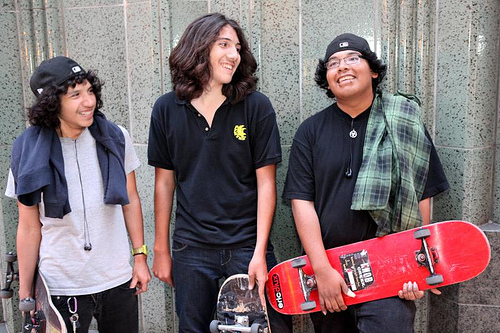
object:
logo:
[233, 122, 248, 142]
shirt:
[147, 86, 282, 250]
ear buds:
[73, 142, 94, 252]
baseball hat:
[30, 55, 87, 99]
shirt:
[352, 90, 430, 235]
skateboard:
[267, 218, 491, 315]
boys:
[4, 14, 450, 331]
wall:
[0, 0, 499, 331]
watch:
[131, 244, 148, 253]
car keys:
[67, 297, 83, 331]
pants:
[50, 280, 140, 331]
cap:
[323, 34, 371, 59]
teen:
[149, 12, 293, 331]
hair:
[169, 12, 258, 103]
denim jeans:
[174, 238, 292, 331]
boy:
[282, 32, 451, 331]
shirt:
[5, 125, 137, 295]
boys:
[148, 13, 449, 331]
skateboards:
[24, 221, 491, 331]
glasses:
[323, 53, 362, 69]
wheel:
[413, 229, 428, 238]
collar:
[175, 90, 235, 138]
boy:
[4, 56, 149, 332]